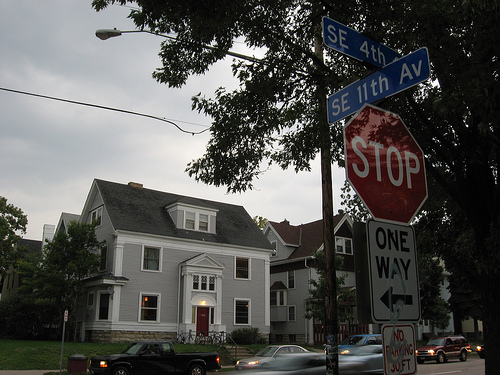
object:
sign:
[339, 100, 435, 230]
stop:
[350, 133, 422, 194]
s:
[350, 135, 370, 181]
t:
[367, 136, 388, 186]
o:
[385, 139, 406, 189]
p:
[402, 149, 423, 193]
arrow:
[380, 285, 418, 314]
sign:
[363, 217, 424, 324]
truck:
[87, 338, 226, 374]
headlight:
[99, 359, 109, 370]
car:
[234, 340, 326, 372]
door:
[194, 308, 212, 339]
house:
[74, 175, 278, 362]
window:
[182, 207, 197, 232]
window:
[198, 211, 210, 234]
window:
[141, 243, 164, 275]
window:
[233, 253, 253, 282]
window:
[138, 292, 160, 322]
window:
[231, 297, 254, 324]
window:
[97, 244, 110, 272]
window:
[89, 205, 106, 229]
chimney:
[126, 180, 149, 192]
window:
[84, 291, 99, 310]